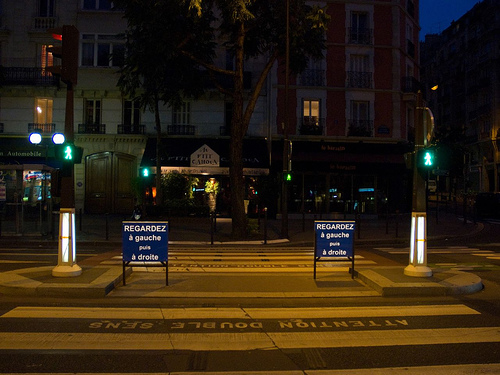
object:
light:
[407, 207, 430, 266]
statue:
[402, 135, 439, 278]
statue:
[183, 147, 231, 216]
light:
[203, 177, 218, 192]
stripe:
[309, 329, 411, 348]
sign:
[314, 214, 356, 266]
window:
[32, 96, 55, 122]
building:
[10, 54, 93, 135]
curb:
[390, 284, 433, 295]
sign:
[189, 149, 221, 168]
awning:
[189, 165, 231, 176]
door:
[83, 153, 135, 217]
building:
[23, 68, 153, 218]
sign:
[122, 219, 170, 270]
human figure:
[423, 150, 435, 167]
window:
[299, 100, 324, 129]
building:
[274, 40, 382, 150]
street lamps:
[25, 130, 67, 147]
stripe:
[116, 300, 373, 320]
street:
[141, 290, 395, 362]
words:
[168, 314, 415, 328]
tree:
[132, 0, 329, 237]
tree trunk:
[224, 114, 250, 237]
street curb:
[176, 239, 272, 248]